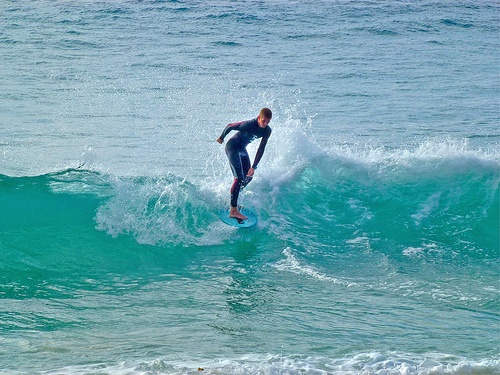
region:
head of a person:
[256, 104, 279, 124]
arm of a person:
[216, 98, 254, 148]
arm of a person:
[253, 142, 278, 158]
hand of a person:
[212, 137, 234, 148]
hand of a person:
[245, 170, 266, 182]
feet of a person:
[220, 205, 256, 221]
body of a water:
[75, 32, 173, 99]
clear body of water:
[88, 33, 207, 121]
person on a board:
[205, 93, 297, 233]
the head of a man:
[235, 82, 299, 132]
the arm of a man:
[197, 116, 238, 158]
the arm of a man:
[211, 116, 263, 151]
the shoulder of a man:
[220, 105, 258, 137]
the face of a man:
[234, 89, 298, 141]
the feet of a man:
[218, 189, 260, 236]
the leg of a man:
[218, 145, 250, 243]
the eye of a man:
[248, 101, 286, 143]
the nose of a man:
[252, 98, 283, 139]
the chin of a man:
[251, 79, 301, 143]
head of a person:
[253, 102, 279, 142]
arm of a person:
[243, 141, 276, 173]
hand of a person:
[220, 136, 225, 150]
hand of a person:
[245, 165, 263, 174]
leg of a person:
[220, 174, 249, 207]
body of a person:
[223, 119, 273, 156]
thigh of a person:
[223, 150, 248, 179]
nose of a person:
[263, 117, 276, 125]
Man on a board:
[212, 181, 267, 231]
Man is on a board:
[215, 178, 260, 233]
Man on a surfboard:
[214, 178, 263, 237]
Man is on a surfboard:
[217, 182, 263, 228]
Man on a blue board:
[209, 177, 264, 232]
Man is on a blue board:
[210, 175, 262, 235]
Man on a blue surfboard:
[212, 175, 259, 235]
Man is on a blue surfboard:
[205, 170, 258, 234]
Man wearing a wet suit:
[214, 114, 276, 209]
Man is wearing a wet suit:
[216, 115, 273, 211]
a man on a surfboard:
[217, 107, 272, 227]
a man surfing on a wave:
[215, 105, 271, 231]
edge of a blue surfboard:
[215, 203, 255, 225]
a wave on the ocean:
[1, 145, 496, 295]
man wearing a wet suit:
[217, 117, 272, 205]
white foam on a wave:
[45, 82, 495, 239]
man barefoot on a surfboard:
[227, 205, 247, 216]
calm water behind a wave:
[1, 0, 497, 71]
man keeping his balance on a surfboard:
[216, 107, 269, 223]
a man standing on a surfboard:
[216, 108, 275, 228]